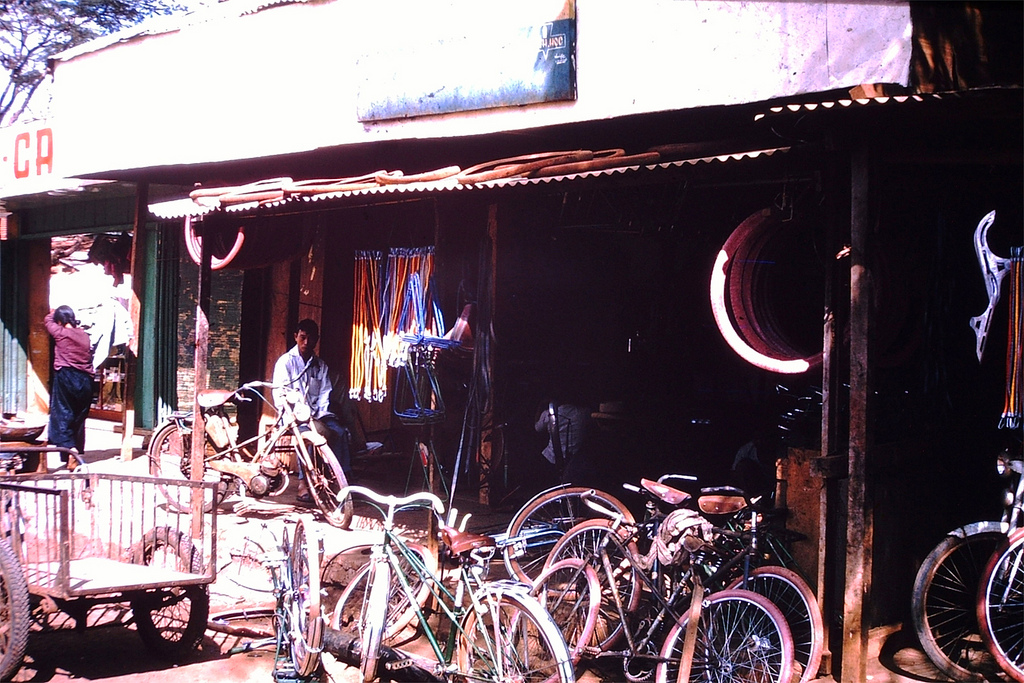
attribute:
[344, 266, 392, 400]
curtain —  Colored